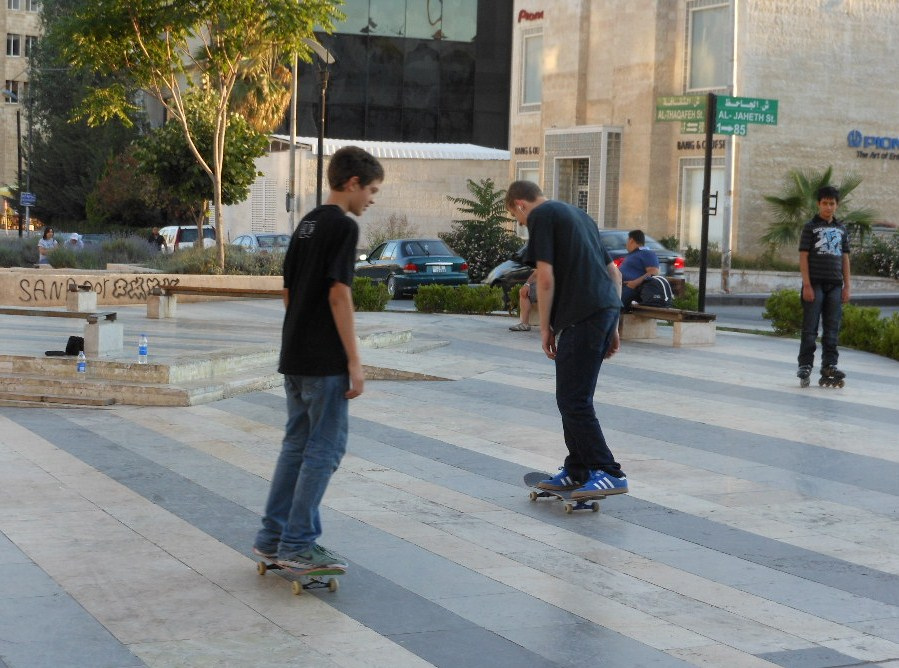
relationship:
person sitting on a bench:
[603, 213, 687, 294] [597, 255, 695, 359]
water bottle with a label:
[138, 334, 149, 365] [136, 347, 155, 363]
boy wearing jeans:
[253, 144, 382, 569] [273, 363, 361, 565]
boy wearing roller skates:
[797, 186, 852, 387] [799, 363, 841, 392]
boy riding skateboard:
[489, 183, 636, 487] [518, 438, 596, 519]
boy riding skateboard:
[253, 144, 382, 569] [240, 536, 338, 598]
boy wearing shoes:
[505, 180, 628, 498] [538, 466, 629, 499]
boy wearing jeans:
[505, 180, 628, 498] [557, 330, 625, 473]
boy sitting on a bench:
[616, 226, 697, 314] [616, 258, 707, 356]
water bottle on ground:
[138, 334, 149, 365] [2, 278, 881, 663]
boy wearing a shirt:
[253, 144, 382, 569] [270, 206, 368, 366]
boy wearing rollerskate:
[797, 186, 852, 387] [794, 359, 815, 391]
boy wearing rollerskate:
[797, 186, 852, 387] [815, 362, 847, 388]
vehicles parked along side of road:
[329, 227, 544, 315] [343, 243, 885, 390]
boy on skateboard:
[253, 144, 382, 569] [246, 536, 352, 598]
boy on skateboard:
[489, 183, 636, 487] [522, 465, 606, 510]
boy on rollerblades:
[797, 186, 852, 387] [797, 362, 844, 389]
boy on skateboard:
[253, 144, 382, 569] [238, 536, 345, 606]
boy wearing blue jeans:
[253, 144, 382, 569] [251, 356, 353, 557]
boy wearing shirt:
[253, 144, 382, 569] [272, 187, 397, 384]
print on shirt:
[815, 225, 849, 264] [794, 210, 856, 308]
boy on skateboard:
[249, 135, 373, 569] [249, 361, 351, 558]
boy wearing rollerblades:
[781, 171, 846, 404] [781, 357, 851, 384]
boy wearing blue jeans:
[253, 144, 382, 569] [261, 366, 357, 558]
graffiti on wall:
[18, 277, 180, 302] [0, 269, 279, 311]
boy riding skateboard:
[505, 180, 628, 498] [527, 470, 626, 510]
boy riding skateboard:
[253, 144, 382, 569] [251, 547, 350, 591]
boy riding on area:
[505, 180, 628, 498] [7, 269, 896, 662]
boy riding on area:
[253, 144, 382, 569] [7, 269, 896, 662]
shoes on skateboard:
[540, 469, 626, 496] [520, 467, 624, 509]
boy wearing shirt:
[253, 144, 382, 569] [278, 205, 360, 377]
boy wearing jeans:
[253, 144, 382, 569] [253, 369, 347, 558]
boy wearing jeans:
[505, 180, 628, 498] [549, 304, 620, 477]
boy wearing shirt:
[505, 180, 628, 498] [523, 202, 622, 322]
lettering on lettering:
[660, 98, 767, 135] [656, 94, 778, 136]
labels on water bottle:
[77, 362, 87, 373] [72, 351, 86, 385]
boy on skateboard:
[253, 144, 382, 569] [257, 559, 348, 596]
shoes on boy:
[252, 549, 345, 571] [253, 144, 382, 569]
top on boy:
[801, 219, 848, 284] [796, 181, 849, 380]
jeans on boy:
[799, 284, 841, 372] [796, 181, 849, 380]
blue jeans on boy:
[253, 374, 348, 561] [253, 144, 382, 569]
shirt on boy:
[278, 205, 360, 377] [253, 144, 382, 569]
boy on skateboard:
[253, 144, 382, 569] [255, 554, 346, 591]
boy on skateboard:
[797, 186, 852, 387] [525, 467, 600, 514]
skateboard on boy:
[524, 471, 607, 513] [797, 186, 852, 387]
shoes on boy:
[538, 466, 629, 499] [797, 186, 852, 387]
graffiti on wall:
[18, 277, 180, 302] [2, 271, 185, 310]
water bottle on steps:
[138, 334, 149, 365] [0, 313, 397, 406]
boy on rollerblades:
[797, 186, 852, 387] [799, 366, 844, 390]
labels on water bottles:
[77, 346, 147, 375] [73, 331, 153, 375]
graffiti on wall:
[23, 276, 194, 302] [2, 266, 281, 308]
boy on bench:
[797, 186, 852, 387] [510, 259, 720, 348]